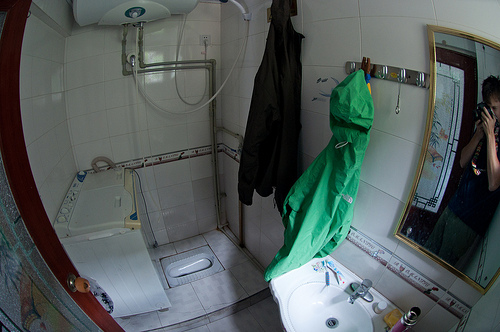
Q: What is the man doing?
A: Taking a pic.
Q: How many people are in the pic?
A: One.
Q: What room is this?
A: Bathroom.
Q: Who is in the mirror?
A: A man.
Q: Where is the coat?
A: On the wall.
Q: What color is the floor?
A: White.